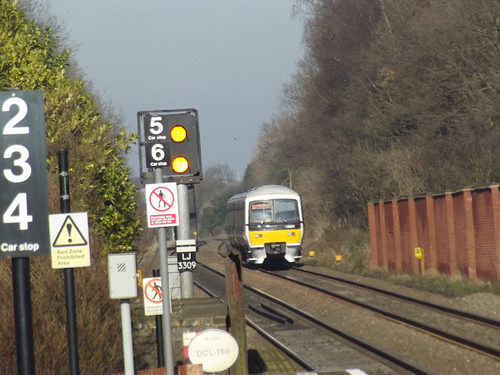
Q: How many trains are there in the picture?
A: One.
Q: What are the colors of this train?
A: White and yellow.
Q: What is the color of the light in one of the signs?
A: Yellow.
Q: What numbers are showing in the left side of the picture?
A: Two three four.